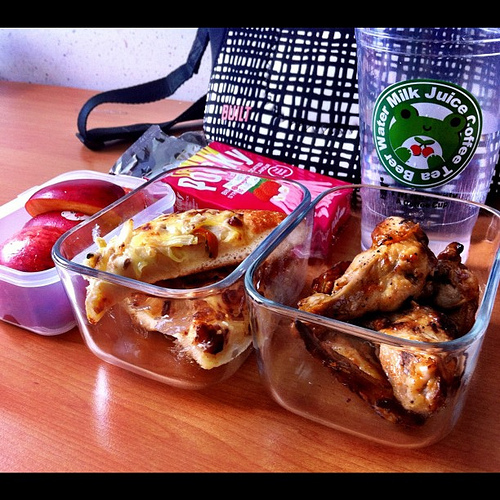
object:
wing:
[302, 217, 433, 309]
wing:
[370, 306, 450, 416]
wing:
[321, 338, 400, 422]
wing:
[421, 239, 483, 338]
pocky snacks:
[172, 142, 277, 194]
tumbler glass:
[358, 29, 500, 260]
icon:
[372, 83, 485, 183]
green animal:
[387, 97, 467, 172]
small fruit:
[422, 144, 432, 158]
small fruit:
[409, 143, 419, 157]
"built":
[213, 104, 255, 120]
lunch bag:
[75, 30, 475, 201]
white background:
[291, 66, 297, 72]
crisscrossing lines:
[265, 54, 314, 113]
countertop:
[0, 77, 500, 475]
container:
[244, 186, 499, 445]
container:
[49, 166, 312, 393]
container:
[0, 167, 179, 338]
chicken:
[82, 207, 297, 372]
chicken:
[290, 216, 480, 430]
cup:
[344, 26, 499, 267]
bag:
[197, 27, 499, 190]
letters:
[218, 100, 252, 121]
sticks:
[130, 136, 295, 205]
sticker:
[59, 205, 95, 222]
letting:
[202, 82, 281, 133]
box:
[148, 143, 353, 263]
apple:
[0, 177, 151, 321]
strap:
[72, 21, 212, 152]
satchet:
[116, 123, 352, 263]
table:
[2, 27, 497, 474]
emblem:
[370, 80, 479, 191]